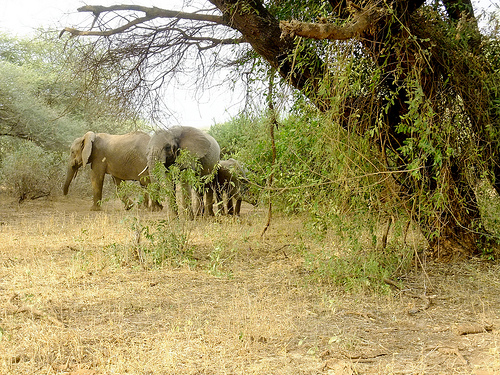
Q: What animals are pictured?
A: Elephants.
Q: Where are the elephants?
A: Under a tree.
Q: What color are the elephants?
A: Gray.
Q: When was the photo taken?
A: During the day.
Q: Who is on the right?
A: Baby elephant.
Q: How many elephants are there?
A: Three.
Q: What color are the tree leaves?
A: Green.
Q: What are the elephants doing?
A: Standing.